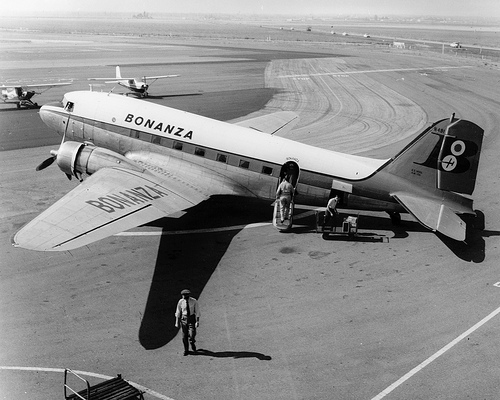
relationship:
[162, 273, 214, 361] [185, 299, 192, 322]
person wearing tie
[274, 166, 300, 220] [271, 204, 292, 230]
person on stairs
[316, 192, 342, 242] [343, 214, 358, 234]
man has package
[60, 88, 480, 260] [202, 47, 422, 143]
plane on runway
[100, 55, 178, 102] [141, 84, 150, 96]
airplane has propeller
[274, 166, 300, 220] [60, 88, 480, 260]
person on plane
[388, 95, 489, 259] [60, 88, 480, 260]
tail on airplane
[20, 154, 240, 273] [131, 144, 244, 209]
wing on left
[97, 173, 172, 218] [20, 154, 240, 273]
bonanza on wing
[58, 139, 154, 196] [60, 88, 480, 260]
engine on plane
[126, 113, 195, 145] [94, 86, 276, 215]
bonanza on fuselage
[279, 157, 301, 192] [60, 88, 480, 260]
door of plane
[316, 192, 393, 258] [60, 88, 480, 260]
man by plane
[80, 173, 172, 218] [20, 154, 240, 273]
bonanza on wing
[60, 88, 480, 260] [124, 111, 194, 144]
plane has bonanza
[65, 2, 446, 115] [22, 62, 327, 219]
field for planes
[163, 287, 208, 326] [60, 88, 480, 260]
pilot by plane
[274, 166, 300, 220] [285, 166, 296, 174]
person going inside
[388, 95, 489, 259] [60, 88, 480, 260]
tail of plane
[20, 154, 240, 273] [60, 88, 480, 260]
wing of plane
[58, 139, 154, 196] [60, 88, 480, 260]
engine of plane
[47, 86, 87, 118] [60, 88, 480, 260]
cockpit of plane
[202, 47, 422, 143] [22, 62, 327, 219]
runway for planes